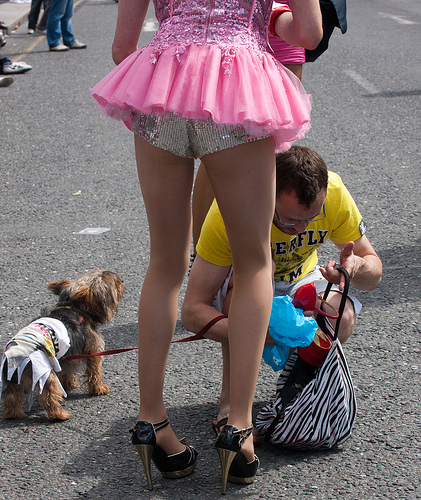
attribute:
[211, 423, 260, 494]
shoe — black, gold, high heeled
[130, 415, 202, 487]
shoe — black, gold, high heeled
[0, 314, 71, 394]
shirt — white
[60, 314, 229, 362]
leash — red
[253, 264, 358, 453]
bag — black, white, zebra striped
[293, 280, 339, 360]
shoe — red, high heeled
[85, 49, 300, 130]
tut — pink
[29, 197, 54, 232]
asphalt — black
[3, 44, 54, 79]
lines — yellow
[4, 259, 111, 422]
dog — small and brown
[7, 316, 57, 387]
outfit — white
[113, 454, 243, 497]
shoes — black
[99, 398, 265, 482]
shoes — black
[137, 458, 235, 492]
heels — gold  spiky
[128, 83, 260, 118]
skirt — short and pink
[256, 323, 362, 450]
bag — zebra print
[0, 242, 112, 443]
dog — small and brown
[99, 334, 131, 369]
leash — red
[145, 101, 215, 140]
panties — shiny and  silver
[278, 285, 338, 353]
shoe — red